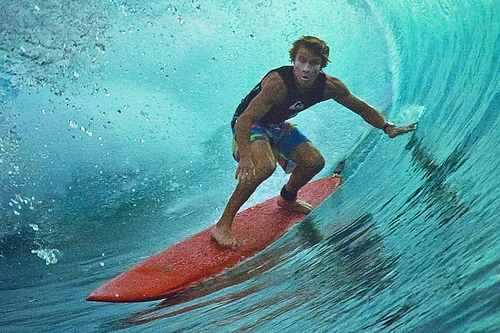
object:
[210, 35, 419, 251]
man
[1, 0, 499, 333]
wave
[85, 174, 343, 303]
surfboard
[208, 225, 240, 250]
foot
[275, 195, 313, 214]
foot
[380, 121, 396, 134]
watch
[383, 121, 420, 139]
hand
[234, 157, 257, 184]
hand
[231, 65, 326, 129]
shirt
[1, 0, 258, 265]
ocean spray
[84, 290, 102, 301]
tip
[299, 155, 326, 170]
knee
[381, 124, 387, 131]
strap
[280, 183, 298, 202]
ankle band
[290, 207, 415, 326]
shadow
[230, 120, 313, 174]
swim trunks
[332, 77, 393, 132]
arm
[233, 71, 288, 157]
arm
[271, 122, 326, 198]
leg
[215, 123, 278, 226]
leg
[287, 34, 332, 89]
head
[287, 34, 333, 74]
hair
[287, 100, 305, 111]
design